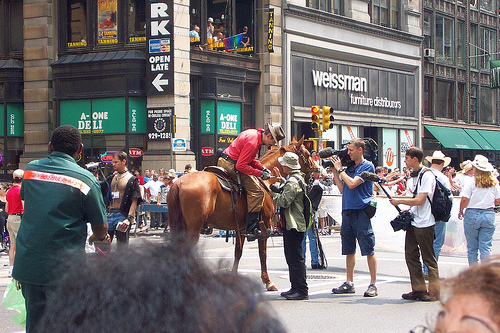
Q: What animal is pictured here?
A: A horse.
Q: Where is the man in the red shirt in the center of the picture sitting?
A: On a horse.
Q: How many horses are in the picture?
A: One.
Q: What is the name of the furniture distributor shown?
A: Weissman.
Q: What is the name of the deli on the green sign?
A: A-one.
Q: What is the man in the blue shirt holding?
A: A movie camera.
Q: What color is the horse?
A: Brown.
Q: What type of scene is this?
A: A street scene.